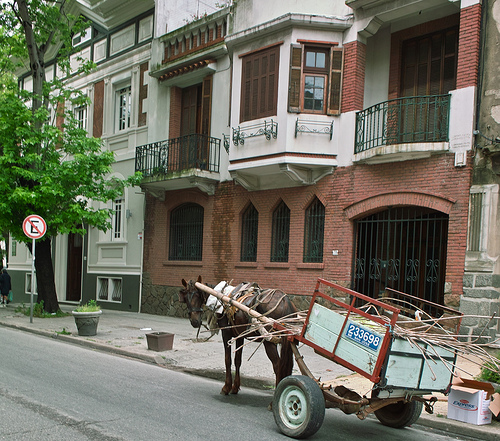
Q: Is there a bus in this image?
A: No, there are no buses.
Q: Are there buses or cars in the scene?
A: No, there are no buses or cars.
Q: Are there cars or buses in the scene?
A: No, there are no buses or cars.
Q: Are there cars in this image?
A: No, there are no cars.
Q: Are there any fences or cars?
A: No, there are no cars or fences.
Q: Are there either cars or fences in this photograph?
A: No, there are no cars or fences.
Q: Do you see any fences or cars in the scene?
A: No, there are no cars or fences.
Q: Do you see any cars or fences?
A: No, there are no cars or fences.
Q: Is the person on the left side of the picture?
A: Yes, the person is on the left of the image.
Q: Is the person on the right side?
A: No, the person is on the left of the image.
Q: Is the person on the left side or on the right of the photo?
A: The person is on the left of the image.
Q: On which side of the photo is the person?
A: The person is on the left of the image.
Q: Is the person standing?
A: Yes, the person is standing.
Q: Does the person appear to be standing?
A: Yes, the person is standing.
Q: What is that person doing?
A: The person is standing.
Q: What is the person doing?
A: The person is standing.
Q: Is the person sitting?
A: No, the person is standing.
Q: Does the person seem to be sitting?
A: No, the person is standing.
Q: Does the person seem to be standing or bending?
A: The person is standing.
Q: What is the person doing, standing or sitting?
A: The person is standing.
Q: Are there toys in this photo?
A: No, there are no toys.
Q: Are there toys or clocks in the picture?
A: No, there are no toys or clocks.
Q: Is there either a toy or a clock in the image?
A: No, there are no toys or clocks.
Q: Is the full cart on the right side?
A: Yes, the cart is on the right of the image.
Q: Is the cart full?
A: Yes, the cart is full.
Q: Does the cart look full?
A: Yes, the cart is full.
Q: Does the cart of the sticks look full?
A: Yes, the cart is full.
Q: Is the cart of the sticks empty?
A: No, the cart is full.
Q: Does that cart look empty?
A: No, the cart is full.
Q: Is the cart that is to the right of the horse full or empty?
A: The cart is full.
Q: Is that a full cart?
A: Yes, that is a full cart.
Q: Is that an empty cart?
A: No, that is a full cart.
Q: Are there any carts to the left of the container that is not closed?
A: Yes, there is a cart to the left of the box.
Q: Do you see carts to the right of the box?
A: No, the cart is to the left of the box.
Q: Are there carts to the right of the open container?
A: No, the cart is to the left of the box.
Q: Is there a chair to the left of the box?
A: No, there is a cart to the left of the box.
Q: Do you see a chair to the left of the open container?
A: No, there is a cart to the left of the box.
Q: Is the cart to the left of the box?
A: Yes, the cart is to the left of the box.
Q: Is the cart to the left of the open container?
A: Yes, the cart is to the left of the box.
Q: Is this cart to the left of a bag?
A: No, the cart is to the left of the box.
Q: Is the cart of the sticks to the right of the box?
A: No, the cart is to the left of the box.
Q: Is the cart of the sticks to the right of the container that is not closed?
A: No, the cart is to the left of the box.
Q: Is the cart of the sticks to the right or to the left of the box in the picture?
A: The cart is to the left of the box.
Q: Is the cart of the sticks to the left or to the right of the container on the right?
A: The cart is to the left of the box.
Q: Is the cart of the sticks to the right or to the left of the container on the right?
A: The cart is to the left of the box.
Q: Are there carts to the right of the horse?
A: Yes, there is a cart to the right of the horse.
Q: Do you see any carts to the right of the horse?
A: Yes, there is a cart to the right of the horse.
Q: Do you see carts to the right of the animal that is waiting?
A: Yes, there is a cart to the right of the horse.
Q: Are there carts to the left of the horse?
A: No, the cart is to the right of the horse.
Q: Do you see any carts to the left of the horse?
A: No, the cart is to the right of the horse.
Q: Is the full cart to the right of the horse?
A: Yes, the cart is to the right of the horse.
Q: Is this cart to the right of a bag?
A: No, the cart is to the right of the horse.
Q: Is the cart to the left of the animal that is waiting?
A: No, the cart is to the right of the horse.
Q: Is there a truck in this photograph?
A: No, there are no trucks.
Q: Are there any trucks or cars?
A: No, there are no trucks or cars.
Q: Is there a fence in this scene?
A: No, there are no fences.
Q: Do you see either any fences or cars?
A: No, there are no fences or cars.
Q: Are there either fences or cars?
A: No, there are no fences or cars.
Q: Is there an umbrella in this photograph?
A: No, there are no umbrellas.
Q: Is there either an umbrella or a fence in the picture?
A: No, there are no umbrellas or fences.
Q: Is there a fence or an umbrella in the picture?
A: No, there are no umbrellas or fences.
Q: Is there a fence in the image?
A: No, there are no fences.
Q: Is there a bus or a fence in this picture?
A: No, there are no fences or buses.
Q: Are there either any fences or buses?
A: No, there are no fences or buses.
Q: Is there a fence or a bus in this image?
A: No, there are no fences or buses.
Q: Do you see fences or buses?
A: No, there are no fences or buses.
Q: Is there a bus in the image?
A: No, there are no buses.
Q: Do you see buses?
A: No, there are no buses.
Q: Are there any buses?
A: No, there are no buses.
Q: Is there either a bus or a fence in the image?
A: No, there are no buses or fences.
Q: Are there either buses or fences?
A: No, there are no buses or fences.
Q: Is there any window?
A: Yes, there is a window.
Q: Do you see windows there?
A: Yes, there is a window.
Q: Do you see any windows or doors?
A: Yes, there is a window.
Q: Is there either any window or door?
A: Yes, there is a window.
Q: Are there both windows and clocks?
A: No, there is a window but no clocks.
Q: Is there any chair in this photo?
A: No, there are no chairs.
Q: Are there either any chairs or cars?
A: No, there are no chairs or cars.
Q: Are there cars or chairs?
A: No, there are no chairs or cars.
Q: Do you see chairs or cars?
A: No, there are no chairs or cars.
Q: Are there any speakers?
A: No, there are no speakers.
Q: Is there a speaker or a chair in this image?
A: No, there are no speakers or chairs.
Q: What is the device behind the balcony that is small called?
A: The device is a screen.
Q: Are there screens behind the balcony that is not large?
A: Yes, there is a screen behind the balcony.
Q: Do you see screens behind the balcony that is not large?
A: Yes, there is a screen behind the balcony.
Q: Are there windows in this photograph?
A: Yes, there is a window.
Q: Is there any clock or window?
A: Yes, there is a window.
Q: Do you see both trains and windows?
A: No, there is a window but no trains.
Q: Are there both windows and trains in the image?
A: No, there is a window but no trains.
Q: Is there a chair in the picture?
A: No, there are no chairs.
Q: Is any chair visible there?
A: No, there are no chairs.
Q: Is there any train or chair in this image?
A: No, there are no chairs or trains.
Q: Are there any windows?
A: Yes, there is a window.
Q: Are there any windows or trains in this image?
A: Yes, there is a window.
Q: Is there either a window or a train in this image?
A: Yes, there is a window.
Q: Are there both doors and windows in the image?
A: Yes, there are both a window and a door.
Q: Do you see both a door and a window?
A: Yes, there are both a window and a door.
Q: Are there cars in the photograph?
A: No, there are no cars.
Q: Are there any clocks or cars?
A: No, there are no cars or clocks.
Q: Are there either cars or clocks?
A: No, there are no cars or clocks.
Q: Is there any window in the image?
A: Yes, there is a window.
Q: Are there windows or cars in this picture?
A: Yes, there is a window.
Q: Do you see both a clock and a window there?
A: No, there is a window but no clocks.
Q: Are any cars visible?
A: No, there are no cars.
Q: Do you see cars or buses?
A: No, there are no cars or buses.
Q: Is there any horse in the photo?
A: Yes, there is a horse.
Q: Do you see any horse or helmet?
A: Yes, there is a horse.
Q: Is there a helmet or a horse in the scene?
A: Yes, there is a horse.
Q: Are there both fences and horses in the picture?
A: No, there is a horse but no fences.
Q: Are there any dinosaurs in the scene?
A: No, there are no dinosaurs.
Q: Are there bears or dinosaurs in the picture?
A: No, there are no dinosaurs or bears.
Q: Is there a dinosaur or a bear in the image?
A: No, there are no dinosaurs or bears.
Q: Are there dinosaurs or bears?
A: No, there are no dinosaurs or bears.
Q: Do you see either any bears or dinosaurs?
A: No, there are no dinosaurs or bears.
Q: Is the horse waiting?
A: Yes, the horse is waiting.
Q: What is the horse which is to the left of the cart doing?
A: The horse is waiting.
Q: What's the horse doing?
A: The horse is waiting.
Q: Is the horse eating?
A: No, the horse is waiting.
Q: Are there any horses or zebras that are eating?
A: No, there is a horse but it is waiting.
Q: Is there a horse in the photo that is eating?
A: No, there is a horse but it is waiting.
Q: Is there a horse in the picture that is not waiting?
A: No, there is a horse but it is waiting.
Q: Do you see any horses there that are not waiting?
A: No, there is a horse but it is waiting.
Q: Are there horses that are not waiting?
A: No, there is a horse but it is waiting.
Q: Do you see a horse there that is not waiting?
A: No, there is a horse but it is waiting.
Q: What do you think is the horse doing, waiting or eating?
A: The horse is waiting.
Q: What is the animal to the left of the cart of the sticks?
A: The animal is a horse.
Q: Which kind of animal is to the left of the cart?
A: The animal is a horse.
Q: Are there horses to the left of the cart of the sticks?
A: Yes, there is a horse to the left of the cart.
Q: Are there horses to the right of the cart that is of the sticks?
A: No, the horse is to the left of the cart.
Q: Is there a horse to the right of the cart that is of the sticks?
A: No, the horse is to the left of the cart.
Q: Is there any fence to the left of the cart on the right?
A: No, there is a horse to the left of the cart.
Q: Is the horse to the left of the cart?
A: Yes, the horse is to the left of the cart.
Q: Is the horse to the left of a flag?
A: No, the horse is to the left of the cart.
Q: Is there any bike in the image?
A: No, there are no bikes.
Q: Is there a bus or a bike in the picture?
A: No, there are no bikes or buses.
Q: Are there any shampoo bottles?
A: No, there are no shampoo bottles.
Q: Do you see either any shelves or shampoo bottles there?
A: No, there are no shampoo bottles or shelves.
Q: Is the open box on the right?
A: Yes, the box is on the right of the image.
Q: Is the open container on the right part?
A: Yes, the box is on the right of the image.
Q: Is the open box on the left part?
A: No, the box is on the right of the image.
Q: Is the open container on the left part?
A: No, the box is on the right of the image.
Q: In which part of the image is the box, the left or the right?
A: The box is on the right of the image.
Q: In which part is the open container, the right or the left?
A: The box is on the right of the image.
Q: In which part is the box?
A: The box is on the right of the image.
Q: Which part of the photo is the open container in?
A: The box is on the right of the image.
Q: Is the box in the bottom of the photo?
A: Yes, the box is in the bottom of the image.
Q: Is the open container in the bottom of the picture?
A: Yes, the box is in the bottom of the image.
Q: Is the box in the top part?
A: No, the box is in the bottom of the image.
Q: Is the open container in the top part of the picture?
A: No, the box is in the bottom of the image.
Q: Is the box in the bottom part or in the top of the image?
A: The box is in the bottom of the image.